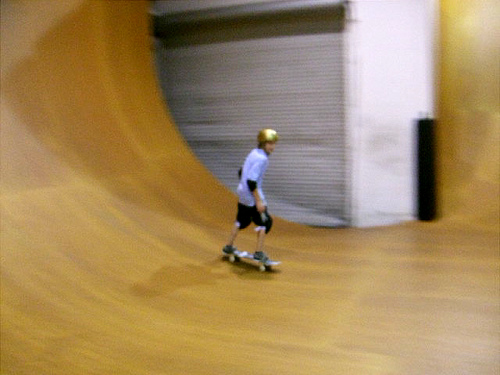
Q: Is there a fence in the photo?
A: No, there are no fences.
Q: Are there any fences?
A: No, there are no fences.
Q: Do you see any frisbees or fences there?
A: No, there are no fences or frisbees.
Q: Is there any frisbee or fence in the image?
A: No, there are no fences or frisbees.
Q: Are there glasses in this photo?
A: No, there are no glasses.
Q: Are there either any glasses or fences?
A: No, there are no glasses or fences.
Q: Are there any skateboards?
A: Yes, there is a skateboard.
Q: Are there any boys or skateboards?
A: Yes, there is a skateboard.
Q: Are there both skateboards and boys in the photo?
A: Yes, there are both a skateboard and a boy.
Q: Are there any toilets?
A: No, there are no toilets.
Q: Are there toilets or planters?
A: No, there are no toilets or planters.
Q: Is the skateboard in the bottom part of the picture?
A: Yes, the skateboard is in the bottom of the image.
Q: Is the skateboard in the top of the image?
A: No, the skateboard is in the bottom of the image.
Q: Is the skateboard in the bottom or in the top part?
A: The skateboard is in the bottom of the image.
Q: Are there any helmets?
A: Yes, there is a helmet.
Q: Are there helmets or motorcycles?
A: Yes, there is a helmet.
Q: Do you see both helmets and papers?
A: No, there is a helmet but no papers.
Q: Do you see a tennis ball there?
A: No, there are no tennis balls.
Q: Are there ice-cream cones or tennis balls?
A: No, there are no tennis balls or ice-cream cones.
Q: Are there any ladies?
A: No, there are no ladies.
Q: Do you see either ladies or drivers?
A: No, there are no ladies or drivers.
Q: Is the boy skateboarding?
A: Yes, the boy is skateboarding.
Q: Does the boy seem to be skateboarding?
A: Yes, the boy is skateboarding.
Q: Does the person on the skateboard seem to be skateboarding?
A: Yes, the boy is skateboarding.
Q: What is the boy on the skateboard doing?
A: The boy is skateboarding.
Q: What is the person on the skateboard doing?
A: The boy is skateboarding.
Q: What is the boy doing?
A: The boy is skateboarding.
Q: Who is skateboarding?
A: The boy is skateboarding.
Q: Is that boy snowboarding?
A: No, the boy is skateboarding.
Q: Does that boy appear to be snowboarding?
A: No, the boy is skateboarding.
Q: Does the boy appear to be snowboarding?
A: No, the boy is skateboarding.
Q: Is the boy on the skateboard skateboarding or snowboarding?
A: The boy is skateboarding.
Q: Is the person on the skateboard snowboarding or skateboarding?
A: The boy is skateboarding.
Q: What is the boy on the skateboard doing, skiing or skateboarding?
A: The boy is skateboarding.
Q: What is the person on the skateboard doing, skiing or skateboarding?
A: The boy is skateboarding.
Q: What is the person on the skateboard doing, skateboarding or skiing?
A: The boy is skateboarding.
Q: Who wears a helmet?
A: The boy wears a helmet.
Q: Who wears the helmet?
A: The boy wears a helmet.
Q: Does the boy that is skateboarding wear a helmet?
A: Yes, the boy wears a helmet.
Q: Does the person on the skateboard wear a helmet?
A: Yes, the boy wears a helmet.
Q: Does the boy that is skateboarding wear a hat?
A: No, the boy wears a helmet.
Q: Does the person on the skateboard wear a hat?
A: No, the boy wears a helmet.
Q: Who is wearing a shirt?
A: The boy is wearing a shirt.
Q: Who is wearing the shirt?
A: The boy is wearing a shirt.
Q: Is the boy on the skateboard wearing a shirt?
A: Yes, the boy is wearing a shirt.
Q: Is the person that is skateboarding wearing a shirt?
A: Yes, the boy is wearing a shirt.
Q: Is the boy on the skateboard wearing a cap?
A: No, the boy is wearing a shirt.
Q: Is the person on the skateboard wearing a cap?
A: No, the boy is wearing a shirt.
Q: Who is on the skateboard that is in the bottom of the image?
A: The boy is on the skateboard.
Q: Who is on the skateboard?
A: The boy is on the skateboard.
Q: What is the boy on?
A: The boy is on the skateboard.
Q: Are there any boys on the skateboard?
A: Yes, there is a boy on the skateboard.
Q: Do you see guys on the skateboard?
A: No, there is a boy on the skateboard.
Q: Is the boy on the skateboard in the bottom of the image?
A: Yes, the boy is on the skateboard.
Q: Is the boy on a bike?
A: No, the boy is on the skateboard.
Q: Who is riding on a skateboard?
A: The boy is riding on a skateboard.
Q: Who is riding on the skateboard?
A: The boy is riding on a skateboard.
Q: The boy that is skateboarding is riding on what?
A: The boy is riding on a skateboard.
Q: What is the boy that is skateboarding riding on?
A: The boy is riding on a skateboard.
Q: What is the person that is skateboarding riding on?
A: The boy is riding on a skateboard.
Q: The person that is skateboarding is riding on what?
A: The boy is riding on a skateboard.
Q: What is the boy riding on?
A: The boy is riding on a skateboard.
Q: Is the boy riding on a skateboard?
A: Yes, the boy is riding on a skateboard.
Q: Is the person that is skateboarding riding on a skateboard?
A: Yes, the boy is riding on a skateboard.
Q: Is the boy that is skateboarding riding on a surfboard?
A: No, the boy is riding on a skateboard.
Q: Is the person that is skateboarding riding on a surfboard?
A: No, the boy is riding on a skateboard.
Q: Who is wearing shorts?
A: The boy is wearing shorts.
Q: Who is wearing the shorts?
A: The boy is wearing shorts.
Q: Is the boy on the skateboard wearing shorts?
A: Yes, the boy is wearing shorts.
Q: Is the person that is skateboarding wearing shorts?
A: Yes, the boy is wearing shorts.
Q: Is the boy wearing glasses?
A: No, the boy is wearing shorts.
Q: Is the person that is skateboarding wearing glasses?
A: No, the boy is wearing shorts.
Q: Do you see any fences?
A: No, there are no fences.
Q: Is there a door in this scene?
A: Yes, there is a door.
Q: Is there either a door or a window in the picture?
A: Yes, there is a door.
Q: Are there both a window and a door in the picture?
A: No, there is a door but no windows.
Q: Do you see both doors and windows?
A: No, there is a door but no windows.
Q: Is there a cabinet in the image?
A: No, there are no cabinets.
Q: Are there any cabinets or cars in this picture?
A: No, there are no cabinets or cars.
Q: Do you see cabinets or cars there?
A: No, there are no cabinets or cars.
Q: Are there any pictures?
A: No, there are no pictures.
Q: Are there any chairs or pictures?
A: No, there are no pictures or chairs.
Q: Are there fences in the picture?
A: No, there are no fences.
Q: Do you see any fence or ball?
A: No, there are no fences or balls.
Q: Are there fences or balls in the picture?
A: No, there are no fences or balls.